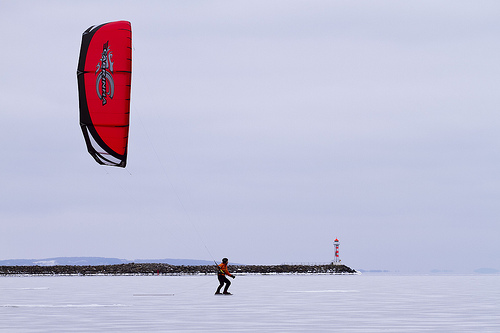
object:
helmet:
[222, 258, 230, 263]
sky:
[0, 0, 500, 270]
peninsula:
[0, 263, 363, 277]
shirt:
[216, 262, 232, 277]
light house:
[333, 237, 341, 263]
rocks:
[132, 265, 133, 267]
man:
[213, 258, 234, 296]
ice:
[0, 274, 500, 333]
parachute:
[77, 20, 130, 166]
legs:
[223, 276, 230, 293]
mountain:
[0, 256, 242, 266]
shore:
[0, 263, 363, 276]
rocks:
[181, 265, 184, 267]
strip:
[0, 272, 361, 277]